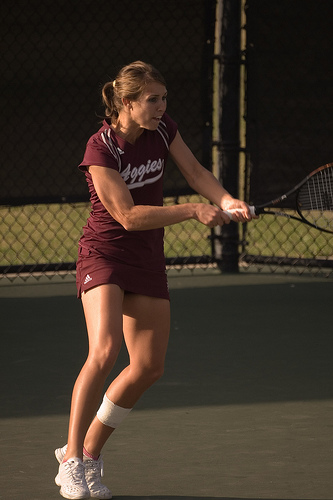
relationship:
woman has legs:
[51, 61, 256, 499] [66, 285, 171, 456]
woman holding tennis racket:
[51, 61, 256, 499] [220, 163, 333, 234]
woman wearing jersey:
[51, 61, 256, 499] [79, 114, 176, 261]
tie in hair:
[111, 78, 118, 89] [96, 60, 167, 129]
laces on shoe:
[68, 458, 86, 484] [55, 457, 90, 499]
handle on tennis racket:
[221, 204, 260, 221] [220, 163, 333, 234]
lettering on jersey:
[120, 157, 167, 188] [79, 114, 176, 261]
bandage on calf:
[96, 393, 131, 429] [90, 366, 152, 453]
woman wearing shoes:
[51, 61, 256, 499] [53, 445, 109, 500]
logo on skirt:
[83, 272, 93, 286] [74, 243, 171, 302]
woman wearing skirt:
[51, 61, 256, 499] [74, 243, 171, 302]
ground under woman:
[2, 270, 332, 499] [51, 61, 256, 499]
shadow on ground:
[1, 280, 333, 417] [2, 270, 332, 499]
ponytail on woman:
[92, 77, 119, 125] [51, 61, 256, 499]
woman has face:
[51, 61, 256, 499] [134, 84, 169, 131]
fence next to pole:
[1, 1, 219, 278] [216, 0, 244, 275]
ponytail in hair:
[92, 77, 119, 125] [96, 60, 167, 129]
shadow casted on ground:
[1, 280, 333, 417] [2, 270, 332, 499]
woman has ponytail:
[51, 61, 256, 499] [92, 77, 119, 125]